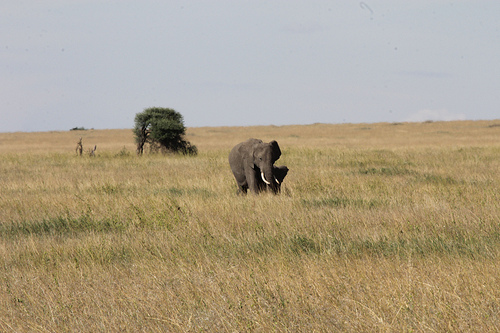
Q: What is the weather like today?
A: It is cloudless.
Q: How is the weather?
A: It is cloudless.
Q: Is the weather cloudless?
A: Yes, it is cloudless.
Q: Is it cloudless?
A: Yes, it is cloudless.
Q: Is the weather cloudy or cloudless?
A: It is cloudless.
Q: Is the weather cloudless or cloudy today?
A: It is cloudless.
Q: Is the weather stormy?
A: No, it is cloudless.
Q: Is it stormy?
A: No, it is cloudless.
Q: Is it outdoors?
A: Yes, it is outdoors.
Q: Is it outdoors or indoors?
A: It is outdoors.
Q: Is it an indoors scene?
A: No, it is outdoors.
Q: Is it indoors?
A: No, it is outdoors.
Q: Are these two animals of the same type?
A: Yes, all the animals are elephants.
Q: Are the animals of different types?
A: No, all the animals are elephants.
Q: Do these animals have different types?
A: No, all the animals are elephants.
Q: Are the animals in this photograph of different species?
A: No, all the animals are elephants.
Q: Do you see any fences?
A: No, there are no fences.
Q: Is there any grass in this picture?
A: Yes, there is grass.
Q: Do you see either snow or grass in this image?
A: Yes, there is grass.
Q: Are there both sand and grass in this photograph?
A: No, there is grass but no sand.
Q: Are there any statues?
A: No, there are no statues.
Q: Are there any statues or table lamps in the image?
A: No, there are no statues or table lamps.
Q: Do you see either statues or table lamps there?
A: No, there are no statues or table lamps.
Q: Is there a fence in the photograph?
A: No, there are no fences.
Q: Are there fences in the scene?
A: No, there are no fences.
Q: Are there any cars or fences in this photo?
A: No, there are no fences or cars.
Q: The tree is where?
A: The tree is in the field.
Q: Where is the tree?
A: The tree is in the field.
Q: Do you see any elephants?
A: Yes, there is an elephant.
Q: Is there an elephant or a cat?
A: Yes, there is an elephant.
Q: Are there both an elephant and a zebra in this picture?
A: No, there is an elephant but no zebras.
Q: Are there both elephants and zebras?
A: No, there is an elephant but no zebras.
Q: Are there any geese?
A: No, there are no geese.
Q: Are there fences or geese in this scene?
A: No, there are no geese or fences.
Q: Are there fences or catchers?
A: No, there are no fences or catchers.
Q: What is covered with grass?
A: The field is covered with grass.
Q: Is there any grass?
A: Yes, there is grass.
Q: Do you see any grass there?
A: Yes, there is grass.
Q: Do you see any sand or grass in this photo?
A: Yes, there is grass.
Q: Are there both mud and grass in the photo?
A: No, there is grass but no mud.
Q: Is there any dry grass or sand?
A: Yes, there is dry grass.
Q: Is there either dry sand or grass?
A: Yes, there is dry grass.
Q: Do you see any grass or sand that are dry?
A: Yes, the grass is dry.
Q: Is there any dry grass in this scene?
A: Yes, there is dry grass.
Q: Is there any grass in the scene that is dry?
A: Yes, there is grass that is dry.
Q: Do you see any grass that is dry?
A: Yes, there is grass that is dry.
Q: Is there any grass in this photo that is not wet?
A: Yes, there is dry grass.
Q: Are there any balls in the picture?
A: No, there are no balls.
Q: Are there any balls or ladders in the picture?
A: No, there are no balls or ladders.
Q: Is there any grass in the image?
A: Yes, there is grass.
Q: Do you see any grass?
A: Yes, there is grass.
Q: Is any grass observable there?
A: Yes, there is grass.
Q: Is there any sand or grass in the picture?
A: Yes, there is grass.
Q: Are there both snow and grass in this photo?
A: No, there is grass but no snow.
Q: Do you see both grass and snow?
A: No, there is grass but no snow.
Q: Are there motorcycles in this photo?
A: No, there are no motorcycles.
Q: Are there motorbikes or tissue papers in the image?
A: No, there are no motorbikes or tissue papers.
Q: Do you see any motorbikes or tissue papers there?
A: No, there are no motorbikes or tissue papers.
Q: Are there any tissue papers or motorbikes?
A: No, there are no motorbikes or tissue papers.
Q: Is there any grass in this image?
A: Yes, there is grass.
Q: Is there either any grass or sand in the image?
A: Yes, there is grass.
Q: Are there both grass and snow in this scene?
A: No, there is grass but no snow.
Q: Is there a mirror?
A: No, there are no mirrors.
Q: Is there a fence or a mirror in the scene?
A: No, there are no mirrors or fences.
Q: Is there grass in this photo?
A: Yes, there is grass.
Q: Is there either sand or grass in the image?
A: Yes, there is grass.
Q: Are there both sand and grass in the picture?
A: No, there is grass but no sand.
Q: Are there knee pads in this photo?
A: No, there are no knee pads.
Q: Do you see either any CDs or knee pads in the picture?
A: No, there are no knee pads or cds.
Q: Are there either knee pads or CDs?
A: No, there are no knee pads or cds.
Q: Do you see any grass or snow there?
A: Yes, there is grass.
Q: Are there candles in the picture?
A: No, there are no candles.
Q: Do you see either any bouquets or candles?
A: No, there are no candles or bouquets.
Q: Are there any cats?
A: No, there are no cats.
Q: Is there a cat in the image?
A: No, there are no cats.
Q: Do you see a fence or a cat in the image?
A: No, there are no cats or fences.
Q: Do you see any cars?
A: No, there are no cars.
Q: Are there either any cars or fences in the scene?
A: No, there are no cars or fences.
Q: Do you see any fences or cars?
A: No, there are no cars or fences.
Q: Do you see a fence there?
A: No, there are no fences.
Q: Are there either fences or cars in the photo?
A: No, there are no fences or cars.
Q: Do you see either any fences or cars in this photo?
A: No, there are no fences or cars.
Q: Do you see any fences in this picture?
A: No, there are no fences.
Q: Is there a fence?
A: No, there are no fences.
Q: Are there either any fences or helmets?
A: No, there are no fences or helmets.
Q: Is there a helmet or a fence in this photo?
A: No, there are no fences or helmets.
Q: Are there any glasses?
A: No, there are no glasses.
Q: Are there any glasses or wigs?
A: No, there are no glasses or wigs.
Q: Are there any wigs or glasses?
A: No, there are no glasses or wigs.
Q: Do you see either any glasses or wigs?
A: No, there are no glasses or wigs.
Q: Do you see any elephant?
A: Yes, there is an elephant.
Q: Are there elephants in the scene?
A: Yes, there is an elephant.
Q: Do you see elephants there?
A: Yes, there is an elephant.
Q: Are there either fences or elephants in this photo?
A: Yes, there is an elephant.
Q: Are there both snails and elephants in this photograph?
A: No, there is an elephant but no snails.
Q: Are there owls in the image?
A: No, there are no owls.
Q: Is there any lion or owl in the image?
A: No, there are no owls or lions.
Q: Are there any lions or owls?
A: No, there are no owls or lions.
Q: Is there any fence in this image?
A: No, there are no fences.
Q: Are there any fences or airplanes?
A: No, there are no fences or airplanes.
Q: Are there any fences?
A: No, there are no fences.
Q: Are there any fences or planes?
A: No, there are no fences or planes.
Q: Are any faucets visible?
A: No, there are no faucets.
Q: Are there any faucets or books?
A: No, there are no faucets or books.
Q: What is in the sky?
A: The clouds are in the sky.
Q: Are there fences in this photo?
A: No, there are no fences.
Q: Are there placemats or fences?
A: No, there are no fences or placemats.